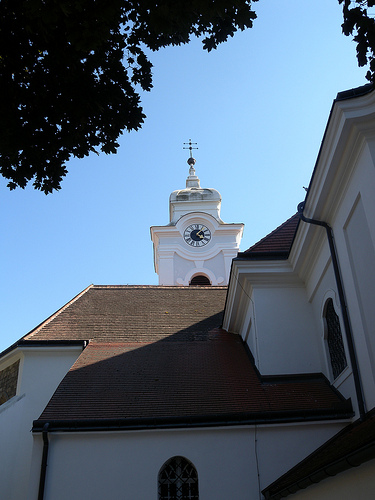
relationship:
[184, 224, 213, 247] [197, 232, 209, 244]
clock has arms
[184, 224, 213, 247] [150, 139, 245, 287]
clock tops steeple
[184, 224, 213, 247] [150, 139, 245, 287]
clock towers above main steeple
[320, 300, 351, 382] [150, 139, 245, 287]
window on steeple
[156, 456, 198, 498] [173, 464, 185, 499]
window shows grating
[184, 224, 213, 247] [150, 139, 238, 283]
clock located on a tower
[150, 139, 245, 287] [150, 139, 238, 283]
steeple has tower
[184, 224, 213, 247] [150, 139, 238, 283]
clock located on tower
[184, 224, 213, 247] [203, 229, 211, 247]
clock has numbers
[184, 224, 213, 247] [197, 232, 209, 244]
clock has clock hands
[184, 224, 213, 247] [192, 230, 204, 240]
clock has center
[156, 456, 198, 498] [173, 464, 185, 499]
window has grating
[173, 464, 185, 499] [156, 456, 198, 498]
grating surrounds window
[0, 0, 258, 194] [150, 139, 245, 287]
tree high to left of steeple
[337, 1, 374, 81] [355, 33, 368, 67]
branch has leaves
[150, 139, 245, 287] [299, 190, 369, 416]
steeple has drain pipe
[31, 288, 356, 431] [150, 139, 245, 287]
roof atop of steeple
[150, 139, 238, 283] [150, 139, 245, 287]
steeple at top of steeple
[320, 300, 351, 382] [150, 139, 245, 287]
window belongs to steeple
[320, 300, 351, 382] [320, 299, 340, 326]
window has rounded top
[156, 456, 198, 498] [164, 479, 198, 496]
white window has bars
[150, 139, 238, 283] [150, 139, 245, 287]
white tower part of steeple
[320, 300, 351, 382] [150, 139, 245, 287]
window on side of steeple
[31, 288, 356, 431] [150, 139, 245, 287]
roof on a steeple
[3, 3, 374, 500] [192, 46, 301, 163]
scene shows sky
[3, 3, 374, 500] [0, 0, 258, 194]
scene shows tree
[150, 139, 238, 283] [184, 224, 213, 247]
white tower has a clock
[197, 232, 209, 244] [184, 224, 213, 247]
hands of a clock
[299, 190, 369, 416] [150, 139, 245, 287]
drain gutter on side of steeple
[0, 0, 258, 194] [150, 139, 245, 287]
tree grows beside of steeple